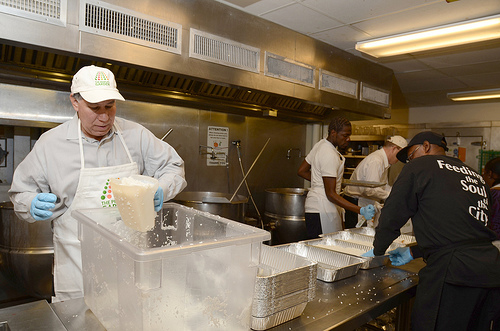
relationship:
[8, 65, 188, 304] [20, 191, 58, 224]
chef wearing glove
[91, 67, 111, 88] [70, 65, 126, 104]
logo on baseball cap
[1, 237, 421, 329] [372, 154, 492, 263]
counter wearing shirt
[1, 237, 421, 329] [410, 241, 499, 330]
counter wearing pants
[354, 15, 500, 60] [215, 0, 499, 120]
ceiling light on ceiling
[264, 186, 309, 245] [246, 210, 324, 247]
containers on stove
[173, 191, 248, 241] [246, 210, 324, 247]
containers on stove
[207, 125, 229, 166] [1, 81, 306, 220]
paper on wall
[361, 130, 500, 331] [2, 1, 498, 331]
man working in food bank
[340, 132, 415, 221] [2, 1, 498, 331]
people working in food bank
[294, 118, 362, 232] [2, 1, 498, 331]
people working in food bank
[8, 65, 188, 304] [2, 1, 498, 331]
chef working in food bank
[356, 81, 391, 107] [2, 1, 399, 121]
vent on wall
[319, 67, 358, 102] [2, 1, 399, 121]
vent on wall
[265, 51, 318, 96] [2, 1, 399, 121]
vent on wall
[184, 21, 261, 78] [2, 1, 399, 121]
vent on wall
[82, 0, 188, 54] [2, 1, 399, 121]
vent on wall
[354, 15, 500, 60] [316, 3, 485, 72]
ceiling light on ceiling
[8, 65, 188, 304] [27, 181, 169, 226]
chef wearing gloves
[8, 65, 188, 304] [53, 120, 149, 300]
chef wearing apron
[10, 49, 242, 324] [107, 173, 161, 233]
chef preparing batter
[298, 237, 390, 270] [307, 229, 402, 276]
aluminum pan full of batter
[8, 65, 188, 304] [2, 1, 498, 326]
chef helping in food bank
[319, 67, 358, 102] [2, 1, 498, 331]
vent over food bank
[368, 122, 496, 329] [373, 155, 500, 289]
man wearing shirt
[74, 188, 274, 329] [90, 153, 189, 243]
container used to prepare batter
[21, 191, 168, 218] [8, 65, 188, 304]
gloves on a chef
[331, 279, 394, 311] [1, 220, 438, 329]
crumbs on a counter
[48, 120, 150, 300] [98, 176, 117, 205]
apron with a logo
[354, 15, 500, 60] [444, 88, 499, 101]
ceiling light on ceiling light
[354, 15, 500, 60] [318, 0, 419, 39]
ceiling light on ceiling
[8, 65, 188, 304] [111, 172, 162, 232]
chef shaking pitcher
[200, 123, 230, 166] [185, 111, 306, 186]
paper on wall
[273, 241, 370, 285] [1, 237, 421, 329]
aluminum pan on counter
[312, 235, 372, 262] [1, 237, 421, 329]
aluminum pan on counter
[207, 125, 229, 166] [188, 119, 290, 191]
paper on wall